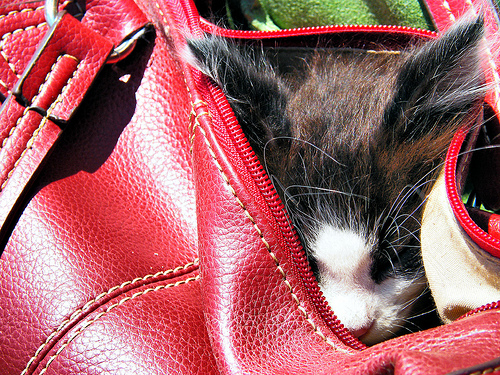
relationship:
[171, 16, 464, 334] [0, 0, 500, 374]
cat in bag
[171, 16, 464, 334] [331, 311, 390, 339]
cat has nose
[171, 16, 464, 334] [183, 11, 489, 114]
cat has ears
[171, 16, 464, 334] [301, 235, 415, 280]
cat has eyes